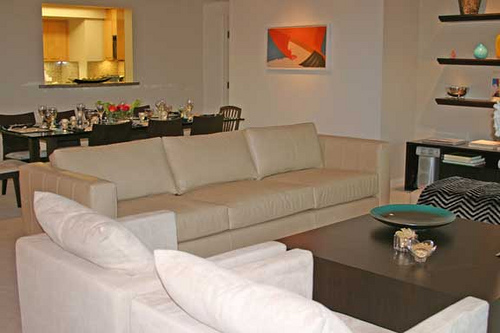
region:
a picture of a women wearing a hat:
[260, 23, 332, 75]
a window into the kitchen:
[37, 3, 137, 88]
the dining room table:
[2, 106, 247, 161]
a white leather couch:
[17, 121, 393, 259]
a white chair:
[15, 177, 286, 332]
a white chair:
[125, 244, 486, 331]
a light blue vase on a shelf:
[474, 40, 489, 60]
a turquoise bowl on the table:
[368, 198, 457, 232]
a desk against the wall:
[403, 135, 498, 190]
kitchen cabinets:
[42, 18, 72, 63]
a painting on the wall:
[247, 17, 343, 88]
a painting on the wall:
[251, 18, 336, 77]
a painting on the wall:
[253, 10, 350, 97]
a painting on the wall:
[256, 8, 346, 88]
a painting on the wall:
[254, 11, 336, 73]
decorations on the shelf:
[434, 19, 495, 122]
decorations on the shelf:
[435, 8, 490, 165]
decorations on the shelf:
[436, 6, 498, 162]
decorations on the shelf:
[433, 2, 498, 139]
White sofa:
[12, 185, 490, 327]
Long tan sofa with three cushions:
[19, 121, 397, 246]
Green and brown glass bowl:
[368, 199, 460, 235]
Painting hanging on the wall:
[258, 17, 329, 73]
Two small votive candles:
[390, 223, 442, 266]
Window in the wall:
[27, 1, 147, 90]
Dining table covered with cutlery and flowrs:
[0, 100, 247, 143]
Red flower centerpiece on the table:
[93, 96, 139, 125]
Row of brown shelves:
[434, 5, 498, 118]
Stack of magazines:
[439, 151, 486, 171]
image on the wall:
[249, 8, 331, 82]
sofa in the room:
[18, 116, 395, 233]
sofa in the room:
[13, 192, 495, 332]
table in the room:
[289, 189, 499, 317]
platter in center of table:
[376, 183, 462, 238]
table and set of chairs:
[0, 93, 265, 217]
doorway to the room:
[192, 5, 232, 110]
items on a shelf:
[428, 26, 495, 59]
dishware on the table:
[4, 99, 195, 118]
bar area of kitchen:
[31, 70, 153, 90]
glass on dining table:
[46, 106, 56, 130]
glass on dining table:
[186, 99, 195, 116]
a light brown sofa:
[9, 114, 384, 254]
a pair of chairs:
[30, 186, 482, 330]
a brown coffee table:
[260, 170, 485, 314]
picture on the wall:
[238, 17, 345, 68]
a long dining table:
[18, 94, 199, 143]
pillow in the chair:
[34, 188, 159, 285]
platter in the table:
[363, 190, 457, 233]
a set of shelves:
[423, 6, 498, 116]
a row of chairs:
[80, 108, 221, 139]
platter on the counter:
[65, 71, 116, 86]